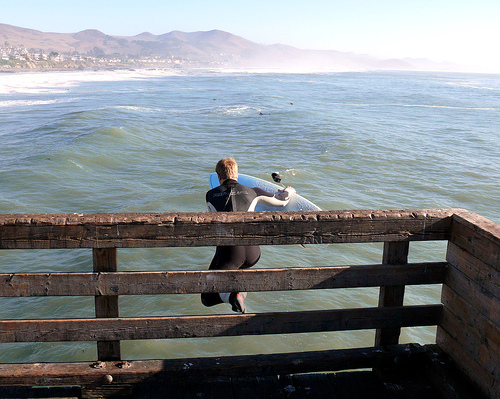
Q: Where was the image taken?
A: It was taken at the ocean.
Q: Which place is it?
A: It is an ocean.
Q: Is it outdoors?
A: Yes, it is outdoors.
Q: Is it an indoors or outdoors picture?
A: It is outdoors.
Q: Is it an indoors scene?
A: No, it is outdoors.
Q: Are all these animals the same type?
A: Yes, all the animals are birds.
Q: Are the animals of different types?
A: No, all the animals are birds.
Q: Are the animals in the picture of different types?
A: No, all the animals are birds.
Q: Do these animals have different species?
A: No, all the animals are birds.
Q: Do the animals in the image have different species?
A: No, all the animals are birds.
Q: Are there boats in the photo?
A: No, there are no boats.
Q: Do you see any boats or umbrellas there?
A: No, there are no boats or umbrellas.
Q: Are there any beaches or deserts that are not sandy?
A: No, there is a beach but it is sandy.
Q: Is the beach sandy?
A: Yes, the beach is sandy.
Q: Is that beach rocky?
A: No, the beach is sandy.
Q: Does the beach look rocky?
A: No, the beach is sandy.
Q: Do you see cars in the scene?
A: No, there are no cars.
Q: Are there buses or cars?
A: No, there are no cars or buses.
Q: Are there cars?
A: No, there are no cars.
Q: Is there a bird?
A: Yes, there are birds.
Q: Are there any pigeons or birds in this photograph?
A: Yes, there are birds.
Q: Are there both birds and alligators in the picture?
A: No, there are birds but no alligators.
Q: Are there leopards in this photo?
A: No, there are no leopards.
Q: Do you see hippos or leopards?
A: No, there are no leopards or hippos.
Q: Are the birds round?
A: Yes, the birds are round.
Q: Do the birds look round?
A: Yes, the birds are round.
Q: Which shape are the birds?
A: The birds are round.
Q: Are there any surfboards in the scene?
A: Yes, there is a surfboard.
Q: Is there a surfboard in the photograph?
A: Yes, there is a surfboard.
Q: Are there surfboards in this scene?
A: Yes, there is a surfboard.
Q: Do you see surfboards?
A: Yes, there is a surfboard.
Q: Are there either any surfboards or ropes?
A: Yes, there is a surfboard.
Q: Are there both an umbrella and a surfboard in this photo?
A: No, there is a surfboard but no umbrellas.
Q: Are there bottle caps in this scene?
A: No, there are no bottle caps.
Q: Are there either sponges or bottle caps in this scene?
A: No, there are no bottle caps or sponges.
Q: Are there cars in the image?
A: No, there are no cars.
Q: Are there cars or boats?
A: No, there are no cars or boats.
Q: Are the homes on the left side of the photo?
A: Yes, the homes are on the left of the image.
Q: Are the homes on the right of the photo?
A: No, the homes are on the left of the image.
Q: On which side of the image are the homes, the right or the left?
A: The homes are on the left of the image.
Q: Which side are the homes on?
A: The homes are on the left of the image.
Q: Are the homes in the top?
A: Yes, the homes are in the top of the image.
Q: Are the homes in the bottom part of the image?
A: No, the homes are in the top of the image.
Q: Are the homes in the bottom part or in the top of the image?
A: The homes are in the top of the image.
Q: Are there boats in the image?
A: No, there are no boats.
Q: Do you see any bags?
A: No, there are no bags.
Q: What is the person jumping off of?
A: The person is jumping off the pier.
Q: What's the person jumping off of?
A: The person is jumping off the pier.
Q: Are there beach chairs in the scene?
A: No, there are no beach chairs.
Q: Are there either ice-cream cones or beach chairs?
A: No, there are no beach chairs or ice-cream cones.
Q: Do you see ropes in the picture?
A: No, there are no ropes.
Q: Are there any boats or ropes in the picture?
A: No, there are no ropes or boats.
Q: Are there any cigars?
A: No, there are no cigars.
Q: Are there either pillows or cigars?
A: No, there are no cigars or pillows.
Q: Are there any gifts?
A: No, there are no gifts.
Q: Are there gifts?
A: No, there are no gifts.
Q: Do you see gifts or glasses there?
A: No, there are no gifts or glasses.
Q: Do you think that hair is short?
A: Yes, the hair is short.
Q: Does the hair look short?
A: Yes, the hair is short.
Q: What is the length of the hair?
A: The hair is short.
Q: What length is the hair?
A: The hair is short.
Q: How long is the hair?
A: The hair is short.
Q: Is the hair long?
A: No, the hair is short.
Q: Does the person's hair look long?
A: No, the hair is short.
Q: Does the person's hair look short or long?
A: The hair is short.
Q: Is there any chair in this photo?
A: No, there are no chairs.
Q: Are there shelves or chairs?
A: No, there are no chairs or shelves.